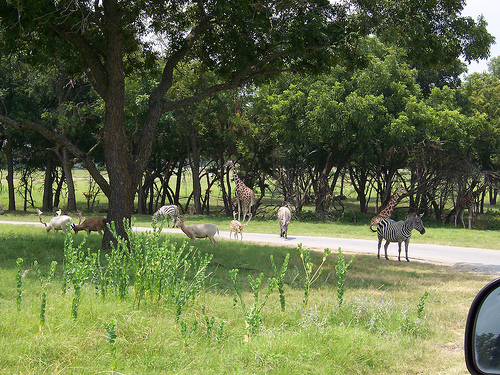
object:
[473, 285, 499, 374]
mirror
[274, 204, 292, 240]
animal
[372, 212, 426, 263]
animal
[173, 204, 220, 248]
animal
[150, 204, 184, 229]
animal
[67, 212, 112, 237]
animal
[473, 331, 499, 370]
reflection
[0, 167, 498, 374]
grass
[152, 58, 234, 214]
tree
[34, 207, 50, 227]
antlers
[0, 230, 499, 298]
shade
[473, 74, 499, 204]
tree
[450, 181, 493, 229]
animal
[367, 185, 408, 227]
animal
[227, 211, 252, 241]
animal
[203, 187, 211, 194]
animal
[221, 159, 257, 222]
animal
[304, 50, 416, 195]
fire hydrant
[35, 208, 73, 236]
animal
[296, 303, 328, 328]
flowers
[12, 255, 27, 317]
tall grass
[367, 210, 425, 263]
animals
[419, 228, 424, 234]
snout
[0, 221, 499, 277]
path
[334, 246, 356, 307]
plants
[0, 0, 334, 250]
tree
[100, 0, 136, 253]
tree trunk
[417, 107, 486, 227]
tree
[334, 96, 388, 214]
tree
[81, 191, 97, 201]
animal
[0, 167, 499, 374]
field